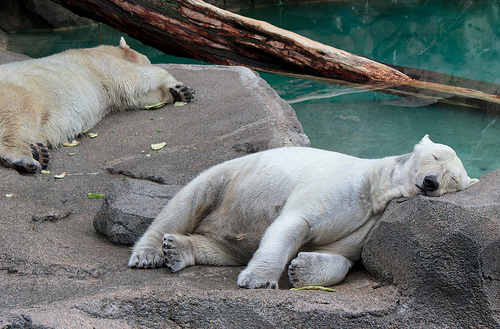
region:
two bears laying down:
[38, 3, 470, 303]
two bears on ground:
[10, 32, 462, 304]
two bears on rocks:
[35, 29, 485, 324]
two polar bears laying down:
[15, 9, 479, 314]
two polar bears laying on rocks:
[1, 25, 478, 317]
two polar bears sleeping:
[24, 15, 466, 303]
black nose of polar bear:
[415, 172, 445, 196]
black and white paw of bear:
[157, 232, 191, 273]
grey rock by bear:
[322, 176, 492, 327]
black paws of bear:
[144, 81, 196, 125]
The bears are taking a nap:
[16, 13, 491, 304]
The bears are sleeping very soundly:
[10, 38, 495, 325]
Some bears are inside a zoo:
[2, 23, 497, 313]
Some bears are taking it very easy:
[5, 27, 490, 327]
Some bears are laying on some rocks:
[10, 20, 480, 316]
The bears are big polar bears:
[6, 32, 486, 322]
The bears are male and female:
[11, 28, 494, 309]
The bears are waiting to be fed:
[6, 7, 482, 320]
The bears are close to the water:
[23, 32, 468, 322]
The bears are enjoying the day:
[14, 37, 479, 304]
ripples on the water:
[291, 78, 353, 118]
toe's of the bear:
[35, 138, 56, 183]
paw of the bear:
[284, 238, 344, 297]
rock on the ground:
[86, 165, 179, 268]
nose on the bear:
[416, 172, 443, 198]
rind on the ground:
[140, 130, 172, 163]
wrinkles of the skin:
[354, 165, 406, 210]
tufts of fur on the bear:
[176, 153, 291, 251]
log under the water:
[386, 63, 498, 126]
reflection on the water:
[353, 85, 450, 112]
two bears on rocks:
[0, 18, 470, 326]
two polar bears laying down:
[1, 15, 476, 327]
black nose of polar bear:
[415, 172, 440, 194]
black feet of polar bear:
[7, 141, 59, 181]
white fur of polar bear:
[284, 156, 355, 211]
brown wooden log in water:
[120, 22, 420, 94]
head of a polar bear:
[406, 124, 476, 199]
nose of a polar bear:
[420, 174, 445, 192]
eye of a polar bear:
[425, 142, 447, 164]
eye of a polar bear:
[446, 170, 471, 190]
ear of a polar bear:
[413, 122, 445, 148]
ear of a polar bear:
[465, 167, 489, 195]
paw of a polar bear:
[273, 225, 384, 307]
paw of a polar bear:
[228, 265, 290, 298]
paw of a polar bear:
[155, 222, 192, 289]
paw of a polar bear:
[125, 237, 176, 273]